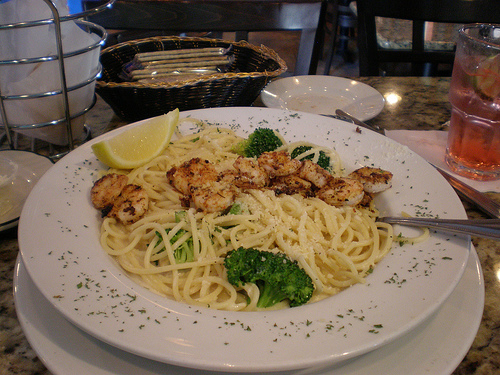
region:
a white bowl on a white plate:
[14, 103, 484, 370]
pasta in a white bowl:
[87, 115, 427, 312]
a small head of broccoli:
[223, 248, 312, 310]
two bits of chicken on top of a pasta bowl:
[90, 172, 147, 220]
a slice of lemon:
[95, 110, 177, 167]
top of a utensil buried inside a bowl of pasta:
[376, 216, 498, 246]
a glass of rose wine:
[443, 23, 499, 182]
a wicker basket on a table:
[101, 33, 286, 125]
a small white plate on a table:
[262, 75, 382, 122]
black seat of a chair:
[357, 3, 496, 73]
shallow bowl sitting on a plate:
[21, 106, 486, 373]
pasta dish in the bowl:
[20, 110, 490, 364]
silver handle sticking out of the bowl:
[375, 208, 499, 238]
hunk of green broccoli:
[228, 248, 315, 312]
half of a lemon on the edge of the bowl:
[87, 107, 189, 167]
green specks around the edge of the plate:
[16, 112, 476, 362]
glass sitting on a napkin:
[383, 18, 499, 210]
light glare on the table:
[380, 85, 403, 110]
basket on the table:
[91, 28, 281, 115]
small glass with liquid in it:
[437, 18, 499, 180]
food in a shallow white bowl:
[23, 104, 493, 369]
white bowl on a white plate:
[17, 104, 482, 374]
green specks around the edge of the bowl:
[14, 104, 467, 366]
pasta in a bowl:
[83, 116, 408, 334]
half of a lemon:
[84, 111, 203, 178]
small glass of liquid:
[438, 22, 498, 191]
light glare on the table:
[384, 90, 403, 105]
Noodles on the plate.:
[93, 113, 433, 312]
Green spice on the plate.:
[22, 105, 474, 369]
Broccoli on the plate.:
[218, 244, 314, 316]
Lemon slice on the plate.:
[90, 106, 181, 171]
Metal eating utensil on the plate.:
[362, 205, 499, 245]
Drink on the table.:
[446, 25, 498, 182]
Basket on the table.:
[96, 30, 290, 125]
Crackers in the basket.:
[92, 39, 283, 114]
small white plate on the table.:
[259, 61, 391, 126]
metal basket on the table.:
[0, 0, 106, 162]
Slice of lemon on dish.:
[82, 106, 188, 166]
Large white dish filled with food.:
[17, 95, 484, 367]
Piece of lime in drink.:
[470, 49, 498, 104]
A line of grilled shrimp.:
[96, 135, 395, 222]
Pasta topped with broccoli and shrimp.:
[102, 123, 414, 312]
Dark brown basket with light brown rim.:
[89, 34, 291, 122]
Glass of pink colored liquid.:
[445, 18, 499, 190]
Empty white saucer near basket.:
[254, 73, 386, 123]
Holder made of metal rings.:
[6, 2, 117, 156]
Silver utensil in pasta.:
[355, 197, 499, 252]